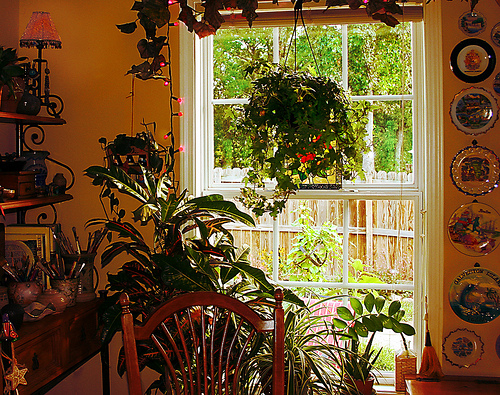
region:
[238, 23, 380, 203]
a hanging plant in front of a window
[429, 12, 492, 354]
several decorative plates on the wall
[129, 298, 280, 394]
brown wood back of the chair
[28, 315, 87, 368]
brown wood cabinet of the shelf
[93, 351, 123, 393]
black metal leg of the shelf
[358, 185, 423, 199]
white frame of the window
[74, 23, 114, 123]
yellow wall of the room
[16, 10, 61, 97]
a small lamp on a shelf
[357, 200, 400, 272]
tan wood fence outside the window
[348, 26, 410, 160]
trees growing outside the window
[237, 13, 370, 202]
plant hanging in front of window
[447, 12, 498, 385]
plates hanging on the wall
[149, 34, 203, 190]
string of lights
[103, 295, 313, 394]
chair in front of plants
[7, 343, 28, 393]
star decoration on the table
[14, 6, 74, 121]
lamp on top of shelf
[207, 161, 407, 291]
fence outside the window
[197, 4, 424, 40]
blinds are rolled up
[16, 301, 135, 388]
door on the table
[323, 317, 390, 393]
plant on the ledge of the window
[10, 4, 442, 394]
Plants are in the shot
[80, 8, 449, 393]
All plants are green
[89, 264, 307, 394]
Chair is made of wood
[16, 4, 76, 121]
A miniature lamp in the corner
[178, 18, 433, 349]
Nothing covering window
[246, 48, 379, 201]
Plant hanging from the cieling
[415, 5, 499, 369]
Plates on the wall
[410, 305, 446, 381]
A broom in the corner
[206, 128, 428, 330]
The person's backyard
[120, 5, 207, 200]
Lights on the plant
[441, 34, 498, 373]
decorative plates on a yellow wall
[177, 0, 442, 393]
window in a dining room with white frame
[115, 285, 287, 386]
back of a dark brown wood dining room chair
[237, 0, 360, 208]
green hanging plant with red flowers in the window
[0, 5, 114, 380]
dark wood and black iron buffet display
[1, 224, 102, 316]
three containers holding many pens and pencils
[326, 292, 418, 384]
curved plant with green leaves in the window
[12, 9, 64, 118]
small lamp with black iron base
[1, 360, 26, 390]
brown star hanging from the buffet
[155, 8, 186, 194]
red lights on a green wire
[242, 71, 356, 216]
Flowers in the photo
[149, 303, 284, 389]
A wooden chair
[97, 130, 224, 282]
A flower in the room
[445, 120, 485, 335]
A wall in the photo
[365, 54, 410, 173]
Glass on the window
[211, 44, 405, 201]
A window in the photo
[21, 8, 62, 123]
A light holder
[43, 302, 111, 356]
A table in the photo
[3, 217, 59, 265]
A picture frame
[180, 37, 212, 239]
A window frame